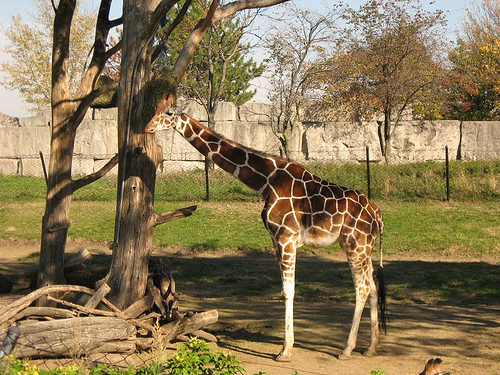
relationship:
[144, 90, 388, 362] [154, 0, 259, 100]
giraffe by tree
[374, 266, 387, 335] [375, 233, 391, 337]
hairs on tail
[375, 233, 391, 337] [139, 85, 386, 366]
tail of giraffe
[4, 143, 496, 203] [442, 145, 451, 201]
fence with post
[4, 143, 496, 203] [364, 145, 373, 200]
fence with post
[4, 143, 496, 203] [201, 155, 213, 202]
fence with post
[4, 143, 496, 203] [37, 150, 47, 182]
fence with post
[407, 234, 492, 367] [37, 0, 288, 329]
shadow of tree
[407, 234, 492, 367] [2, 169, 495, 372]
shadow on ground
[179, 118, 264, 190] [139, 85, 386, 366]
neck of giraffe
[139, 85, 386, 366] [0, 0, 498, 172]
giraffe standing in forest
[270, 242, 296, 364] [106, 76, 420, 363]
leg of giraffe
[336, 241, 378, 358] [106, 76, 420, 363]
leg of giraffe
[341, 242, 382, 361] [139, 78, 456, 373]
leg of giraffe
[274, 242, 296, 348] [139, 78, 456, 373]
leg of giraffe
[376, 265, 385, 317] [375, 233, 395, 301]
fringes on tail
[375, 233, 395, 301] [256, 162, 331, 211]
tail of giraffe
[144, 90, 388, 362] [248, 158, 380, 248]
giraffe has spots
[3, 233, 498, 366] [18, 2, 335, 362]
shadows of trees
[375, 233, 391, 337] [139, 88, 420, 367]
tail of giraffe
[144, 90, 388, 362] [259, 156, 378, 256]
giraffe has spots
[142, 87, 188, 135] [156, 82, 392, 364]
head of giraffe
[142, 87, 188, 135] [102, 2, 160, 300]
head next to trunk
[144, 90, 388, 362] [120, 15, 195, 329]
giraffe near trunk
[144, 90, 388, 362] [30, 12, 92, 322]
giraffe near trunk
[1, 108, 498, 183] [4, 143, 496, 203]
rocks behind fence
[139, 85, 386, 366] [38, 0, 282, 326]
giraffe standing next to trees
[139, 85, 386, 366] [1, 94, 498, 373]
giraffe in giraffe sanctuary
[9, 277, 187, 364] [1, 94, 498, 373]
wooden logs in giraffe sanctuary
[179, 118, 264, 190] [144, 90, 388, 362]
neck of giraffe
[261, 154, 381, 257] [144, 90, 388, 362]
torso of giraffe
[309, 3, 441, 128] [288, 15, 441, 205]
foilage of tree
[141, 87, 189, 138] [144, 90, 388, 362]
head of giraffe